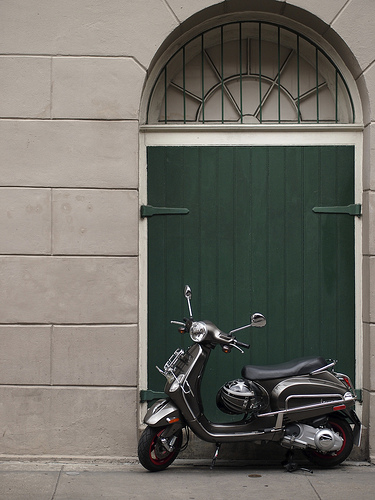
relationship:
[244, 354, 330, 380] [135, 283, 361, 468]
seat on scooter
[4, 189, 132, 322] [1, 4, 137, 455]
bricks on wall